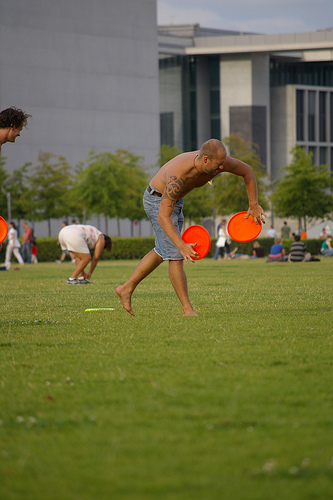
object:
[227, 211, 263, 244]
frisbee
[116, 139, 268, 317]
man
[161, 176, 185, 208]
tattoo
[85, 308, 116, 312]
frisbee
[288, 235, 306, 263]
person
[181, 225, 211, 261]
frisbee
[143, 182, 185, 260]
shorts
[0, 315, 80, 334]
patch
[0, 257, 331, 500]
grass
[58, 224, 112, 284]
woman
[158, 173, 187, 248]
arm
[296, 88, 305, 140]
window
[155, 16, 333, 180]
building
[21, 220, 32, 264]
person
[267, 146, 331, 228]
tree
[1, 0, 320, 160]
background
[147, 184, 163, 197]
belt